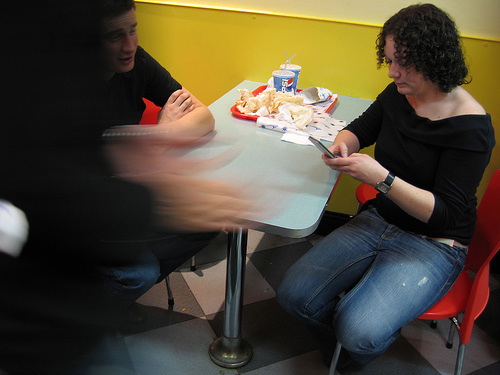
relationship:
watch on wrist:
[374, 172, 394, 193] [371, 170, 389, 191]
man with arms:
[41, 5, 220, 175] [88, 55, 220, 162]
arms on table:
[88, 55, 220, 162] [95, 64, 378, 373]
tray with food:
[231, 79, 341, 124] [255, 91, 306, 111]